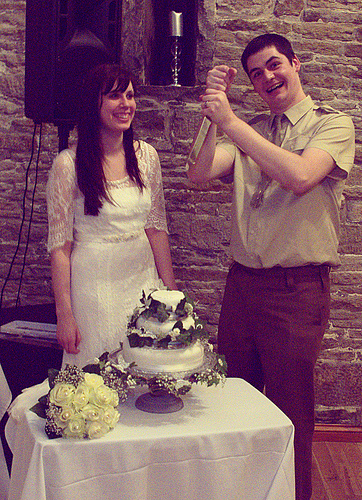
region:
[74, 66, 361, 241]
Two people are standing.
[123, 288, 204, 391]
Wedding cake is in table.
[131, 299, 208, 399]
Cake is white and green color.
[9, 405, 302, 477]
Table cloth is white color.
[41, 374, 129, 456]
White rose bouquet in table.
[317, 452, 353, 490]
Floor is brown color.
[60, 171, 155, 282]
Girl is wearing white dress.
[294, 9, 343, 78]
Wall is brick wall.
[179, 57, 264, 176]
Man is holding knife.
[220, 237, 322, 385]
Man is wearing brown pant.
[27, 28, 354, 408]
a recently married couple ready to cut the cake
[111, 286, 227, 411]
a three tiered wedding cake decorated with flowers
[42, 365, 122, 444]
a bouquet of white roses sitting on the table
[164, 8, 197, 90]
a candle in a decorative silver holder in a nook in the wall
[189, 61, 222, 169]
a silver knife the man is holding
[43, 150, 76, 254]
a lace sleeve on the bride's wedding dress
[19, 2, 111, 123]
a large black speaker behind the bride's head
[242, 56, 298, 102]
the groom's bright smiling face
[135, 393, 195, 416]
the base of pedestal holding the cake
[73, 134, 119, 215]
the bride's wispy long hair on her dress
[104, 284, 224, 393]
wedding cake decorated with flowers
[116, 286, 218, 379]
three tiered wedding cake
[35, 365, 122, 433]
bouquet of white roses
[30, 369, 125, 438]
bridal bouquet resting on table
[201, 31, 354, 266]
man playfully holding cake knife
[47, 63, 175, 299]
bride in white dress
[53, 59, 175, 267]
bride with long dark hair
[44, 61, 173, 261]
bride laughing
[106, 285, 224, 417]
wedding cake displayed on pedestal cake stand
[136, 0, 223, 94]
candle on pedestal displayed in small alcove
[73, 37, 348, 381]
two people in photo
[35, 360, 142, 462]
white rose bouquet in photo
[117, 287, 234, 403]
white wedding cake with leaves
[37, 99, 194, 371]
woman in white wedding dress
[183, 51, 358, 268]
smiling man holding knife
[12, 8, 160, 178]
speaker behind bride in photo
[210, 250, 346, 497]
man wearing black dress pants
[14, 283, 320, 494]
cake and flowers on white table cloth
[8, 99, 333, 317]
stone wall behind people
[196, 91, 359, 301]
man in tan shirt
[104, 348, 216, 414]
wedding cake on pedestal cake plate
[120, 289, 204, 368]
cake has three tiers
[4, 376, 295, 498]
bouquet on white tablecloth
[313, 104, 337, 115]
epaulet on man's shirt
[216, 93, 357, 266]
man wearing tan shirt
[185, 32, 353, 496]
man standing next to cake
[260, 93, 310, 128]
collar on man's shirt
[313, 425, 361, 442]
baseboard visible behind man